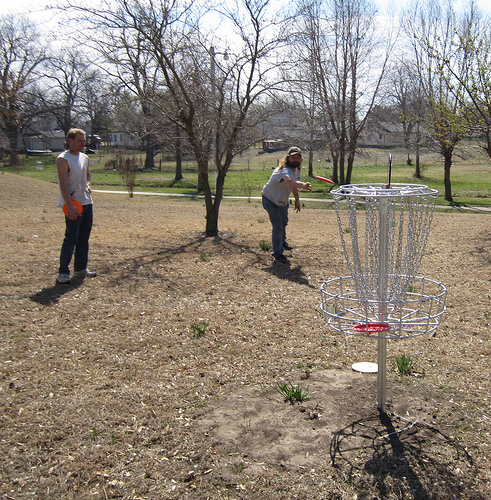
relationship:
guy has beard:
[262, 144, 314, 266] [287, 159, 302, 169]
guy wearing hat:
[262, 144, 314, 266] [284, 147, 303, 158]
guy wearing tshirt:
[262, 144, 314, 266] [261, 169, 295, 204]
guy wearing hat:
[262, 144, 314, 266] [284, 139, 302, 158]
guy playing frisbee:
[262, 144, 314, 266] [355, 314, 390, 337]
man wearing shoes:
[57, 126, 97, 284] [48, 262, 100, 283]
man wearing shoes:
[57, 126, 97, 284] [55, 273, 72, 283]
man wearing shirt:
[57, 126, 97, 284] [60, 150, 93, 202]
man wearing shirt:
[57, 126, 97, 284] [56, 149, 93, 206]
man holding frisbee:
[57, 126, 97, 284] [61, 198, 83, 221]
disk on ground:
[348, 359, 380, 375] [1, 173, 489, 498]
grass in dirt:
[273, 375, 310, 405] [3, 167, 477, 498]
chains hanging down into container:
[327, 187, 442, 324] [313, 182, 452, 350]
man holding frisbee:
[44, 100, 109, 357] [59, 200, 83, 216]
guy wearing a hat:
[262, 144, 314, 266] [285, 143, 304, 164]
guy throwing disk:
[262, 144, 314, 266] [312, 167, 342, 186]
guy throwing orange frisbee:
[255, 145, 319, 261] [290, 172, 355, 199]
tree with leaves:
[416, 85, 487, 197] [409, 33, 489, 141]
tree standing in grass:
[416, 85, 487, 197] [378, 155, 481, 190]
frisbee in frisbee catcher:
[350, 310, 394, 337] [313, 134, 455, 437]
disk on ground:
[350, 359, 380, 372] [133, 333, 379, 491]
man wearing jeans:
[57, 126, 97, 284] [58, 199, 98, 280]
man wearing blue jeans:
[57, 126, 97, 284] [63, 204, 96, 280]